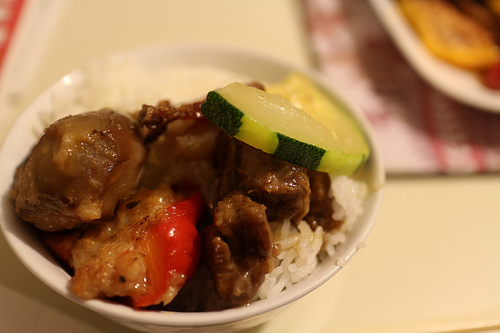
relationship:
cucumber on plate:
[210, 86, 345, 161] [366, 170, 390, 229]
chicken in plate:
[92, 204, 192, 308] [366, 170, 390, 229]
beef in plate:
[37, 120, 147, 194] [366, 170, 390, 229]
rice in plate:
[294, 227, 335, 279] [366, 170, 390, 229]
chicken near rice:
[92, 204, 192, 308] [294, 227, 335, 279]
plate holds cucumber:
[366, 170, 390, 229] [210, 86, 345, 161]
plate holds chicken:
[366, 170, 390, 229] [92, 204, 192, 308]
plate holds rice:
[366, 170, 390, 229] [294, 227, 335, 279]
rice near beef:
[294, 227, 335, 279] [37, 120, 147, 194]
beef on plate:
[37, 120, 147, 194] [366, 170, 390, 229]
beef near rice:
[37, 120, 147, 194] [294, 227, 335, 279]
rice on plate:
[294, 227, 335, 279] [366, 170, 390, 229]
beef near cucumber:
[37, 120, 147, 194] [210, 86, 345, 161]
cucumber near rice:
[210, 86, 345, 161] [294, 227, 335, 279]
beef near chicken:
[37, 120, 147, 194] [92, 204, 192, 308]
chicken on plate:
[92, 204, 192, 308] [366, 170, 390, 229]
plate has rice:
[366, 170, 390, 229] [294, 227, 335, 279]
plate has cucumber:
[366, 170, 390, 229] [210, 86, 345, 161]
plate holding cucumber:
[366, 170, 390, 229] [210, 86, 345, 161]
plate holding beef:
[366, 170, 390, 229] [37, 120, 147, 194]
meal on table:
[18, 68, 358, 315] [5, 0, 497, 329]